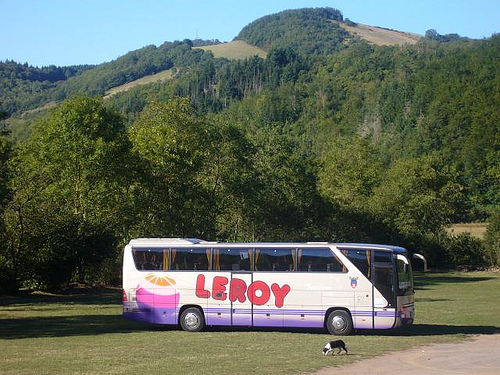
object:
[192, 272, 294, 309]
word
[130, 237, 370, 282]
windows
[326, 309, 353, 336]
wheels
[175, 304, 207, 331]
wheels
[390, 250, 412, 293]
window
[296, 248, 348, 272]
windows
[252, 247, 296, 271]
windows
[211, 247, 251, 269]
windows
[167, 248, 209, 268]
windows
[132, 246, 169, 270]
windows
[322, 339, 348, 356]
dog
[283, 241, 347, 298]
windows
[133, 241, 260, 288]
windows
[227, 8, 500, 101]
hills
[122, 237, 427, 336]
bus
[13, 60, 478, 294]
tall trees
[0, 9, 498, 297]
trees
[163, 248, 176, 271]
curtains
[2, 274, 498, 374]
grass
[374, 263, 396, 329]
door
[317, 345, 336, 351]
markings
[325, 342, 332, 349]
markings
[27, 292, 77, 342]
shadow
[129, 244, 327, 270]
windows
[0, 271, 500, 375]
field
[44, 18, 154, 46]
skies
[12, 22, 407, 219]
scene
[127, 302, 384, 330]
stripes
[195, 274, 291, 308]
logo